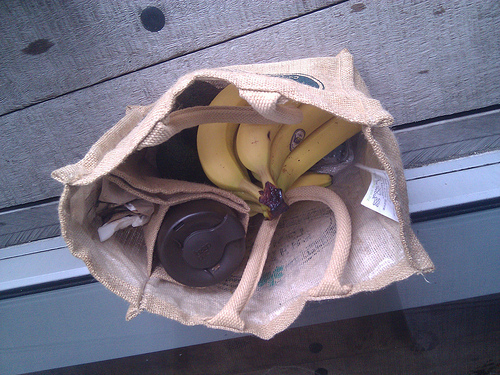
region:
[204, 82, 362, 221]
a bush of bananas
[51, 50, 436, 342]
a light brown burlap bag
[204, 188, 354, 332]
a burlap bag handle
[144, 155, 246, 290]
a brown plastic container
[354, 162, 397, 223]
a white product tag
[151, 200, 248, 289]
Black round plastic top.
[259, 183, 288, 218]
Brown top of the bananas.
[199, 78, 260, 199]
The longest yellow visible banana.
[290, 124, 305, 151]
A sticker on the bananas.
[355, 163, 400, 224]
A white tag on the inside of a bag.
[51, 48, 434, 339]
A reusable sack with bananas.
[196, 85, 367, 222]
A bunch of yellow bananas.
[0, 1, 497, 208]
Two wood slats.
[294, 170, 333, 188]
A small yellow barely visible banana.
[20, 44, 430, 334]
burlap shopping bad with handles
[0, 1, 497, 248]
aged grey wood board table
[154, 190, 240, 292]
black capped travel mug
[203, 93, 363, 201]
yellow bunch of bananas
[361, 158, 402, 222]
lable in the burlap bag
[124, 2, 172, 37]
a round knothole in a board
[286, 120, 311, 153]
sticker on a banana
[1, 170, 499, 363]
an edge painted in light grey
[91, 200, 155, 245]
a bit of crumpled white paper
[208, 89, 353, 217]
The bag has bananas in it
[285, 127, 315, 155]
The sticker on the banana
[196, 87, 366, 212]
The bananas are yellow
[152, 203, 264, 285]
The bag has a mug in it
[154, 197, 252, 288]
The mug has a black cover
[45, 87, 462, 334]
The bag is a light brown bag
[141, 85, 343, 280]
The bag has a banana and a mug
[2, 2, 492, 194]
The table is made of wood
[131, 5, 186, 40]
There are black spots on the wood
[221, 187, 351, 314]
the handle of the bag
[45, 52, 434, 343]
open burlap bag with handles inside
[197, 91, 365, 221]
bunch of yellow bananas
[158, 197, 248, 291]
blank lid and flap of container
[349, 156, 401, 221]
white label attached to hem of bag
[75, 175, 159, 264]
rumpled brown and white material in bag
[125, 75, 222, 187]
dark object next to bananas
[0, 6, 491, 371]
worn wooden boards with black marks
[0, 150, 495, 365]
white and blue trim on edge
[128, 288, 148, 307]
two large stitches at seam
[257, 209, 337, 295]
ink from front of bag showing on back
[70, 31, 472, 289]
this is a bag of food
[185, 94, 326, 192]
this is a fruit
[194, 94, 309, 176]
these are bananas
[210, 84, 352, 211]
the bananas are bunched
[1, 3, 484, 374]
a scene during the day time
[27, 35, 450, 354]
a brown bag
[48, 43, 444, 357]
a bag containing some items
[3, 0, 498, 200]
a wooden floor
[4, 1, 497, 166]
a wooden plank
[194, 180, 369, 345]
a bag handle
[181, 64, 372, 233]
some yellow bananas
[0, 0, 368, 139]
a crack on floor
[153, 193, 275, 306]
a black lid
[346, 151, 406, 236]
a white tag